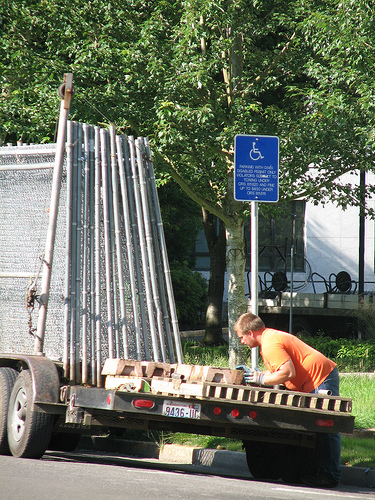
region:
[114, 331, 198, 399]
Cinder blocks.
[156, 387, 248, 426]
License plate on trailer.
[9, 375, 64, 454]
Trailer tire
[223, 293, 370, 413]
Man wearing gloves.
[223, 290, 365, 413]
Man with an orange shirt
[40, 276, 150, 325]
Chain link fence stacked on the back of the trailer.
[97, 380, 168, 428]
Back lights on the trailer.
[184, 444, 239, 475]
Curb on the side of the street.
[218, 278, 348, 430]
Man working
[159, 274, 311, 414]
Man breaking down and loading a fence.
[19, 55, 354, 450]
man working with a trailer.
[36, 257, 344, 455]
man loading a trailer with products.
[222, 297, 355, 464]
a man wearing an orange shirt.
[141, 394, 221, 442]
license plate to a trailer.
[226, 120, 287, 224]
blue handicapped sign in public.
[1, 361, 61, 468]
tires to a work trailer.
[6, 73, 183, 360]
sections of fence stacked together.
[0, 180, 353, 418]
sections of fence loaded on trailer.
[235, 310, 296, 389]
man working with gloves.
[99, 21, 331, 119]
some healthy green leaves.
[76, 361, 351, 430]
pallets on the trailer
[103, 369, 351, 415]
man is near the pallets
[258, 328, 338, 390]
man is wearing orange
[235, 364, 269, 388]
man is wearing gloves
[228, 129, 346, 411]
man is next to sign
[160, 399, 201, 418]
license plate has numbers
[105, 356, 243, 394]
blocks on top of pallets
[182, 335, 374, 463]
grass is behind the man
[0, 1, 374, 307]
tree is near the sign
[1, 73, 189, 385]
fence on top of trailer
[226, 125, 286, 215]
blue handicapped parking sign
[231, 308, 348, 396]
man in a bright orange shirt moving bricks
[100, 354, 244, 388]
dusty red colored bricks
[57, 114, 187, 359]
rows of metal poles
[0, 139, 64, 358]
chain-link fence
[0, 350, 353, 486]
a trailer loaded with construction supplies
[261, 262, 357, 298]
metal lawn chairs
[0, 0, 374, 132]
bright green tree leaves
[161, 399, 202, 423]
red white and blue license plate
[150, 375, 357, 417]
a yellow wooden pallet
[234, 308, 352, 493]
man bent over truck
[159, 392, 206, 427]
state of Louisiana license late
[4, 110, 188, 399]
fencing material on back of truck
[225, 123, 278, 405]
handicapped parking sign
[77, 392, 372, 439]
six visible lights on truck back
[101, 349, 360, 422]
cement blocks on back of truck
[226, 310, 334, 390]
man wearing orange tshirt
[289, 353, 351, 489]
man wearing blue jeans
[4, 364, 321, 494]
truck parked along road curb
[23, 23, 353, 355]
large green shade tree in yard